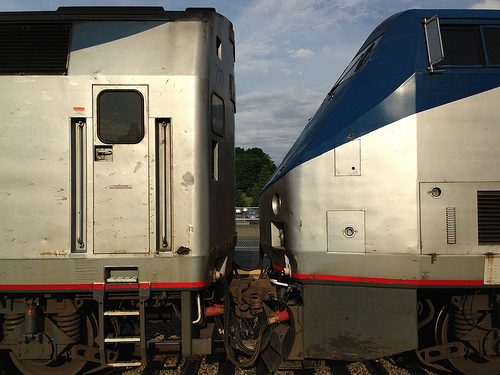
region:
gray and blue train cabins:
[0, 8, 498, 301]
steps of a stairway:
[98, 265, 146, 373]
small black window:
[98, 85, 158, 147]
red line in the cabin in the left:
[0, 255, 232, 296]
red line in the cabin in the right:
[270, 265, 498, 290]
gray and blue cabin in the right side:
[287, 2, 499, 313]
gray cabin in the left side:
[3, 10, 232, 295]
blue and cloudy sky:
[224, 2, 415, 162]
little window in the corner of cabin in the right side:
[473, 190, 498, 252]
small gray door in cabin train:
[87, 79, 151, 261]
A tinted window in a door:
[92, 85, 146, 147]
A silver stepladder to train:
[92, 285, 147, 374]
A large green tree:
[237, 146, 269, 205]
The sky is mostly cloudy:
[237, 8, 314, 143]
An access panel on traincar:
[322, 204, 367, 259]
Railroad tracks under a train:
[166, 359, 301, 374]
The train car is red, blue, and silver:
[379, 10, 498, 301]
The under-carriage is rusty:
[5, 293, 84, 371]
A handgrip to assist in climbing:
[152, 118, 174, 253]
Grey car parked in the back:
[243, 209, 258, 226]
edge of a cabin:
[204, 213, 212, 229]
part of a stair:
[125, 216, 132, 236]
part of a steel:
[156, 332, 175, 352]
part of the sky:
[271, 111, 281, 129]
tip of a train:
[248, 159, 261, 171]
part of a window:
[106, 110, 124, 142]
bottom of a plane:
[356, 330, 381, 336]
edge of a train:
[181, 336, 211, 343]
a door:
[94, 88, 159, 255]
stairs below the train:
[97, 286, 145, 372]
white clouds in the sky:
[237, 3, 318, 109]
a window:
[450, 20, 491, 66]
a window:
[95, 95, 148, 137]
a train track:
[147, 358, 274, 373]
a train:
[0, 7, 496, 277]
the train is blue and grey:
[326, 22, 486, 262]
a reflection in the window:
[110, 110, 140, 140]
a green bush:
[235, 145, 275, 178]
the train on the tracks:
[13, 10, 498, 307]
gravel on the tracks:
[188, 361, 210, 373]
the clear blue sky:
[343, 25, 358, 35]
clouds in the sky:
[253, 85, 290, 134]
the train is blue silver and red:
[4, 5, 498, 295]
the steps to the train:
[85, 283, 158, 370]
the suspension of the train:
[5, 306, 85, 356]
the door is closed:
[86, 83, 154, 251]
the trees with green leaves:
[232, 150, 264, 205]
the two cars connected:
[224, 276, 280, 336]